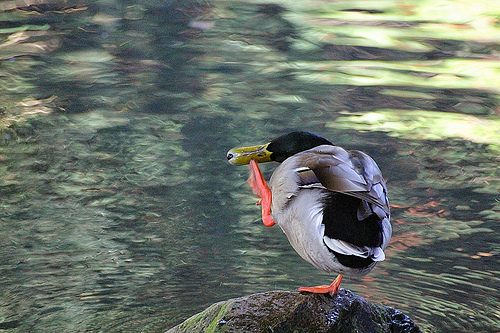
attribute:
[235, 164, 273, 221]
feet — orange, bright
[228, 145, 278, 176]
beak — yellow, green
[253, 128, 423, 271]
duck — standing, scratching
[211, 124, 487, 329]
duck — grey, balancing, standing, cleaning, small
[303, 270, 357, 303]
leg — orange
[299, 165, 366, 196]
feather — gray, grey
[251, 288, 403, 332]
stone — wet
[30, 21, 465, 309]
photo — blurry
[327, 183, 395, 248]
feathers — black